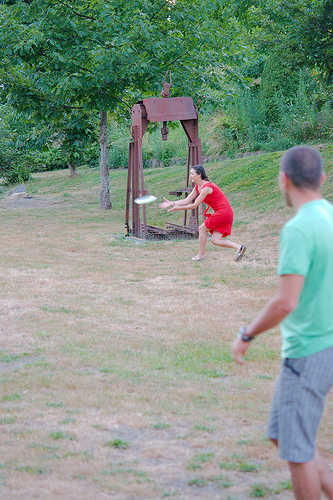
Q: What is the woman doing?
A: Women trying to catch a frisbee.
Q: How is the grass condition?
A: Dying.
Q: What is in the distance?
A: Trees and other plants.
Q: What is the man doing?
A: A man standing and playing frisbee in a green t shirt.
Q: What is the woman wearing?
A: A woman in a red dress.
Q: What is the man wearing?
A: A man wearing gray striped shorts.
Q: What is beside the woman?
A: A tall brown structure standing in a field of grass.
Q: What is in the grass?
A: Dirt.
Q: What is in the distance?
A: Thick green shrubbery standing before a forest.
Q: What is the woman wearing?
A: The dress.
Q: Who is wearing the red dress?
A: The woman.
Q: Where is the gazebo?
A: In the yard.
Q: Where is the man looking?
A: At the woman.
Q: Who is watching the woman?
A: The man.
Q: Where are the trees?
A: In the distance.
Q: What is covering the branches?
A: The leaves.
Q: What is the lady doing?
A: Playing frisbee.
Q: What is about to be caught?
A: The frisbee.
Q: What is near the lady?
A: A brown structure.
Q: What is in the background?
A: Bushes and trees.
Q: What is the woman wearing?
A: A red dress.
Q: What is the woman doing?
A: About to catch a frisbee.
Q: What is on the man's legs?
A: Blue shorts with white stripes.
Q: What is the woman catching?
A: Frisbee.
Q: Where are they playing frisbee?
A: Yard.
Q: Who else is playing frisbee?
A: Man.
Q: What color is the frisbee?
A: White.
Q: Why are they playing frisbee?
A: Entertainment.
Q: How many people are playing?
A: Two.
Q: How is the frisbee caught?
A: Hands.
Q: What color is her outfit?
A: Red.